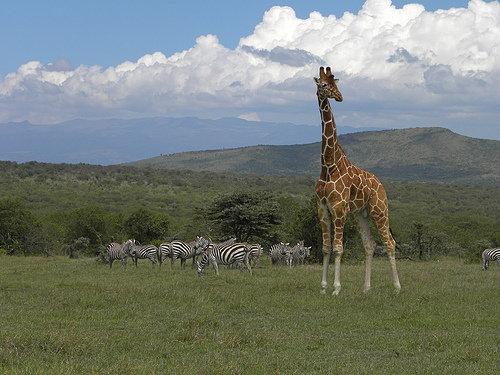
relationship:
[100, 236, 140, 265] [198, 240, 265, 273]
zebra with stripes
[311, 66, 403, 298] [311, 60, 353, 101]
giraffe with its head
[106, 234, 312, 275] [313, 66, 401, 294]
zebra group behind giraffe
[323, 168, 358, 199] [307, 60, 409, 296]
spots on giraffe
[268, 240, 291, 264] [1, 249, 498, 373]
zebra in field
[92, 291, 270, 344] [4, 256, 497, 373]
grass on ground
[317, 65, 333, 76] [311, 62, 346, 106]
horns on head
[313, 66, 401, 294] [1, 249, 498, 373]
giraffe on field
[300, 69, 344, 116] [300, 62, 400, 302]
head on giraffe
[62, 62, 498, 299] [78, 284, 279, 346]
animals in field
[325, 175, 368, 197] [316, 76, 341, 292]
brown spots on giraffe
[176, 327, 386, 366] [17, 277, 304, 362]
grass on ground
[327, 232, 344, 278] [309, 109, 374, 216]
leg on giraffe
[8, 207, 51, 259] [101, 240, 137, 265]
tree behind zebra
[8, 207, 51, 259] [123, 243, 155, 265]
tree behind zebra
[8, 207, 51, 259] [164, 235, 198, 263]
tree behind zebra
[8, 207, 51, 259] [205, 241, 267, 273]
tree behind zebra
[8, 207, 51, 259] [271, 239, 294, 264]
tree behind zebra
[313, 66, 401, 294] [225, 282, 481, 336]
giraffe standing field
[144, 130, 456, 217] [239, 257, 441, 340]
hillside covered grass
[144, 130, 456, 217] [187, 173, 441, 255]
hillside covered trees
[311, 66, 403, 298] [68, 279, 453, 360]
giraffe standing grass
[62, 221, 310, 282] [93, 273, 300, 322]
zebras standing grass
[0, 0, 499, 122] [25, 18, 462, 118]
clouds in sky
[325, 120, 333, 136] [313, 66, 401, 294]
spot on giraffe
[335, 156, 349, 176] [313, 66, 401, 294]
spot on giraffe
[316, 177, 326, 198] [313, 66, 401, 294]
spot on giraffe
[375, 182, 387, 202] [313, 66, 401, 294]
spot on giraffe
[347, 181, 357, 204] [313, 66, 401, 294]
spot on giraffe